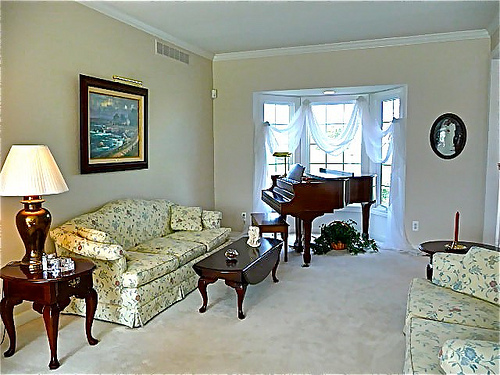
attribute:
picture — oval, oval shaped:
[429, 111, 468, 161]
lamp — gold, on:
[1, 147, 72, 273]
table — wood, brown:
[194, 232, 286, 319]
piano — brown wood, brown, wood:
[262, 168, 380, 268]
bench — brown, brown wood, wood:
[246, 209, 293, 266]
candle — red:
[224, 246, 240, 268]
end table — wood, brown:
[3, 254, 100, 369]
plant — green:
[306, 221, 381, 255]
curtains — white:
[254, 95, 395, 172]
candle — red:
[445, 208, 468, 252]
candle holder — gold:
[445, 236, 470, 253]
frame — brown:
[71, 65, 153, 176]